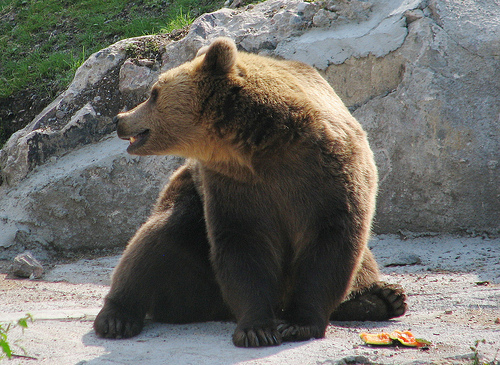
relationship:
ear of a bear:
[148, 85, 165, 105] [89, 45, 410, 346]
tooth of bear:
[124, 134, 136, 145] [89, 45, 410, 346]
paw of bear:
[233, 310, 281, 351] [89, 45, 410, 346]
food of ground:
[358, 329, 428, 351] [10, 240, 497, 363]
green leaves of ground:
[3, 310, 38, 364] [10, 240, 497, 363]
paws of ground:
[95, 285, 405, 349] [10, 240, 497, 363]